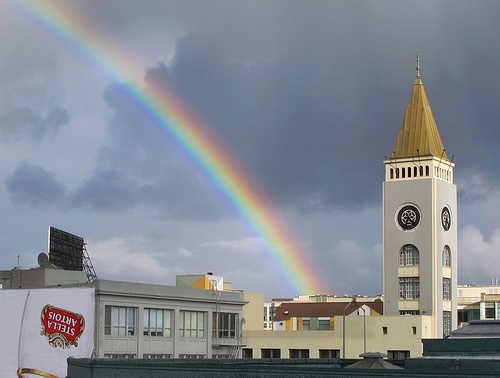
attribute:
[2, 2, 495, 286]
sky — cloudy, blue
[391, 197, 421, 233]
clock — black, white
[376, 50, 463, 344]
tower — grey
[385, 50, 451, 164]
roof — gold, geometric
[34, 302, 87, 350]
billboard — large, empty, white, red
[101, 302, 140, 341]
windows — squared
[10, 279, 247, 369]
building — square, tall, church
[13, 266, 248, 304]
roof — top, brown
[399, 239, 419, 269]
window — arched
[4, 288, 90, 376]
ad — upside down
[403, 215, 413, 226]
hands — black